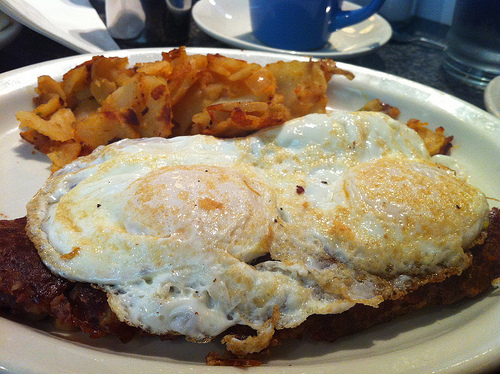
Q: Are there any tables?
A: Yes, there is a table.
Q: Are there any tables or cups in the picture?
A: Yes, there is a table.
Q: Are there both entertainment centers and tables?
A: No, there is a table but no entertainment centers.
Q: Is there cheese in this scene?
A: No, there is no cheese.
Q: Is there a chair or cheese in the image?
A: No, there are no cheese or chairs.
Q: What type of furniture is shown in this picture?
A: The furniture is a table.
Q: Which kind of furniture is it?
A: The piece of furniture is a table.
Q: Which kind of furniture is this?
A: This is a table.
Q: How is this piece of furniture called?
A: This is a table.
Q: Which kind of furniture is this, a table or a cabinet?
A: This is a table.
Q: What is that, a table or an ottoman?
A: That is a table.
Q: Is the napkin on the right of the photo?
A: No, the napkin is on the left of the image.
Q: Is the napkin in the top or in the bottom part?
A: The napkin is in the top of the image.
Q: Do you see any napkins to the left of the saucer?
A: Yes, there is a napkin to the left of the saucer.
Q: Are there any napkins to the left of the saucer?
A: Yes, there is a napkin to the left of the saucer.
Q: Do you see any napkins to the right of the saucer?
A: No, the napkin is to the left of the saucer.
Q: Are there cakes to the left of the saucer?
A: No, there is a napkin to the left of the saucer.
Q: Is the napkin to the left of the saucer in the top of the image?
A: Yes, the napkin is to the left of the saucer.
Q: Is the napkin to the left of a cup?
A: No, the napkin is to the left of the saucer.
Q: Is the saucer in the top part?
A: Yes, the saucer is in the top of the image.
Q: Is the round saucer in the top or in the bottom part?
A: The saucer is in the top of the image.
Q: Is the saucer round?
A: Yes, the saucer is round.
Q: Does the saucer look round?
A: Yes, the saucer is round.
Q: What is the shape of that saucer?
A: The saucer is round.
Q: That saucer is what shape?
A: The saucer is round.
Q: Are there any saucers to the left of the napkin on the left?
A: No, the saucer is to the right of the napkin.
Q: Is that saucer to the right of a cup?
A: No, the saucer is to the right of the napkin.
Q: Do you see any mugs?
A: Yes, there is a mug.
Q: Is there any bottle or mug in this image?
A: Yes, there is a mug.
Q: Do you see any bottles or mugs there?
A: Yes, there is a mug.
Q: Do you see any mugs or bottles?
A: Yes, there is a mug.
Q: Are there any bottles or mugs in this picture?
A: Yes, there is a mug.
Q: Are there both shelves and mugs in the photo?
A: No, there is a mug but no shelves.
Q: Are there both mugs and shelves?
A: No, there is a mug but no shelves.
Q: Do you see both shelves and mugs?
A: No, there is a mug but no shelves.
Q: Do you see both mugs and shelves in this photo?
A: No, there is a mug but no shelves.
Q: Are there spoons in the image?
A: No, there are no spoons.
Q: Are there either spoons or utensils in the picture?
A: No, there are no spoons or utensils.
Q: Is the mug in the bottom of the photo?
A: No, the mug is in the top of the image.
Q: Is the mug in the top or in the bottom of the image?
A: The mug is in the top of the image.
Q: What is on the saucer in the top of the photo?
A: The mug is on the saucer.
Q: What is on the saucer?
A: The mug is on the saucer.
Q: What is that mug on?
A: The mug is on the saucer.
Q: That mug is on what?
A: The mug is on the saucer.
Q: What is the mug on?
A: The mug is on the saucer.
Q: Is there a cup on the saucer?
A: No, there is a mug on the saucer.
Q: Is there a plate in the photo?
A: Yes, there is a plate.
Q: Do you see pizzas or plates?
A: Yes, there is a plate.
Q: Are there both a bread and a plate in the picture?
A: No, there is a plate but no breads.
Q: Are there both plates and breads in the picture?
A: No, there is a plate but no breads.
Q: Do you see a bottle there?
A: No, there are no bottles.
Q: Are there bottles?
A: No, there are no bottles.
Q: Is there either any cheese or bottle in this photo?
A: No, there are no bottles or cheese.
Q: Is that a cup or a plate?
A: That is a plate.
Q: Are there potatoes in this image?
A: Yes, there are potatoes.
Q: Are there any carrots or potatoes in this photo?
A: Yes, there are potatoes.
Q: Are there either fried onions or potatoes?
A: Yes, there are fried potatoes.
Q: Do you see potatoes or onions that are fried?
A: Yes, the potatoes are fried.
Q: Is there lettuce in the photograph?
A: No, there is no lettuce.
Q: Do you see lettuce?
A: No, there is no lettuce.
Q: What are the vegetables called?
A: The vegetables are potatoes.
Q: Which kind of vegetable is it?
A: The vegetables are potatoes.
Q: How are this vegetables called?
A: These are potatoes.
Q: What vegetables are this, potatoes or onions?
A: These are potatoes.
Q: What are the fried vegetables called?
A: The vegetables are potatoes.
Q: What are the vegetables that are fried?
A: The vegetables are potatoes.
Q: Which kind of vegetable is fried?
A: The vegetable is potatoes.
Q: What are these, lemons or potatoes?
A: These are potatoes.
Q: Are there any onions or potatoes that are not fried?
A: No, there are potatoes but they are fried.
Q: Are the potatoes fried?
A: Yes, the potatoes are fried.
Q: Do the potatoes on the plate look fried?
A: Yes, the potatoes are fried.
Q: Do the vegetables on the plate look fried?
A: Yes, the potatoes are fried.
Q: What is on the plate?
A: The potatoes are on the plate.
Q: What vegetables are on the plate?
A: The vegetables are potatoes.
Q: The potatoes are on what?
A: The potatoes are on the plate.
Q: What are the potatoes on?
A: The potatoes are on the plate.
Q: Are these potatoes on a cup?
A: No, the potatoes are on the plate.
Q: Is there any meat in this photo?
A: Yes, there is meat.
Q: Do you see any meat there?
A: Yes, there is meat.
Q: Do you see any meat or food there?
A: Yes, there is meat.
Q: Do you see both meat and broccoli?
A: No, there is meat but no broccoli.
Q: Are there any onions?
A: No, there are no onions.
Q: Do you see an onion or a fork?
A: No, there are no onions or forks.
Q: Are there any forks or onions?
A: No, there are no onions or forks.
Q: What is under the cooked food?
A: The meat is under the egg.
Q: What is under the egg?
A: The meat is under the egg.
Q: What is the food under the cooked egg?
A: The food is meat.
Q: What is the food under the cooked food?
A: The food is meat.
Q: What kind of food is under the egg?
A: The food is meat.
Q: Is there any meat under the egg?
A: Yes, there is meat under the egg.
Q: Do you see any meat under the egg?
A: Yes, there is meat under the egg.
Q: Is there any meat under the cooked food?
A: Yes, there is meat under the egg.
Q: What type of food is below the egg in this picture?
A: The food is meat.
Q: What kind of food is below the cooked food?
A: The food is meat.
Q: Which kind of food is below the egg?
A: The food is meat.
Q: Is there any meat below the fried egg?
A: Yes, there is meat below the egg.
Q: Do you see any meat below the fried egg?
A: Yes, there is meat below the egg.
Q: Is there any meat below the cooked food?
A: Yes, there is meat below the egg.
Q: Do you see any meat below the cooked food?
A: Yes, there is meat below the egg.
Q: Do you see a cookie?
A: No, there are no cookies.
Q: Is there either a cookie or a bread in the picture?
A: No, there are no cookies or breads.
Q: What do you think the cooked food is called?
A: The food is an egg.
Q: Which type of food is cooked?
A: The food is an egg.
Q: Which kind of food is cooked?
A: The food is an egg.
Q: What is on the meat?
A: The egg is on the meat.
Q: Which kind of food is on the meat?
A: The food is an egg.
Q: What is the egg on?
A: The egg is on the meat.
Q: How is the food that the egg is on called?
A: The food is meat.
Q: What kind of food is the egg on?
A: The egg is on the meat.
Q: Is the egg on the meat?
A: Yes, the egg is on the meat.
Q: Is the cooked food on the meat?
A: Yes, the egg is on the meat.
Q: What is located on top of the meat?
A: The egg is on top of the meat.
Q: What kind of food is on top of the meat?
A: The food is an egg.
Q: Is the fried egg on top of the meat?
A: Yes, the egg is on top of the meat.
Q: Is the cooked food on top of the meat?
A: Yes, the egg is on top of the meat.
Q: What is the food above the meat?
A: The food is an egg.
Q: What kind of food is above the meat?
A: The food is an egg.